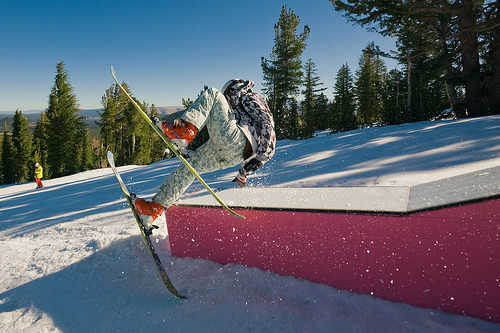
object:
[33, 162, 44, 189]
skier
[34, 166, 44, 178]
jacket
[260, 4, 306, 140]
tree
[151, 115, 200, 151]
ski boot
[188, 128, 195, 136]
accent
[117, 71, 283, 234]
skier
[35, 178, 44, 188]
pants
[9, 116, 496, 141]
horizon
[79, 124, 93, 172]
trees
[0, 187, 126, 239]
shadows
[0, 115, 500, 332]
snow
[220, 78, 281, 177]
jacket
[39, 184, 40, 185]
red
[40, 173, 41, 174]
yellow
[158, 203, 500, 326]
base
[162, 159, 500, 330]
platform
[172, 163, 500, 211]
top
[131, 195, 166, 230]
snow boot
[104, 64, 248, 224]
ski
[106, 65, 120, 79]
end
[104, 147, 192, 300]
ski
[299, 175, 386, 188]
foot prints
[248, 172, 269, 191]
snow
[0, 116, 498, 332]
mountain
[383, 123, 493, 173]
shadow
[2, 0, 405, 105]
sky